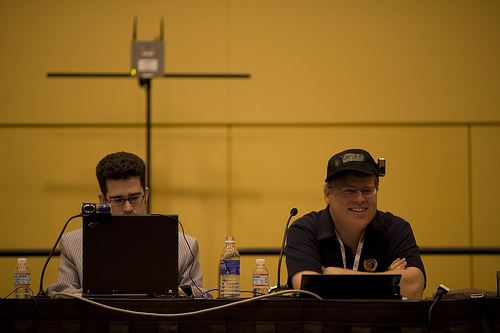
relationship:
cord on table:
[133, 302, 206, 321] [0, 292, 495, 331]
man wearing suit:
[275, 146, 421, 301] [43, 215, 215, 300]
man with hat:
[275, 146, 421, 301] [323, 146, 387, 180]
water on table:
[219, 233, 244, 303] [0, 292, 495, 331]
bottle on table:
[217, 235, 239, 297] [0, 293, 495, 328]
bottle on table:
[250, 256, 266, 293] [0, 293, 495, 328]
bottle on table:
[12, 256, 29, 296] [0, 293, 495, 328]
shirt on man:
[283, 208, 427, 302] [268, 138, 446, 309]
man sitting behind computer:
[62, 145, 215, 302] [65, 208, 192, 296]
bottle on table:
[217, 235, 239, 297] [1, 298, 498, 331]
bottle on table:
[250, 256, 266, 293] [1, 298, 498, 331]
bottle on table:
[12, 256, 29, 296] [1, 298, 498, 331]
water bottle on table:
[218, 235, 240, 294] [0, 293, 495, 328]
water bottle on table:
[253, 257, 268, 293] [0, 293, 495, 328]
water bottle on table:
[14, 251, 29, 294] [0, 293, 495, 328]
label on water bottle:
[218, 259, 240, 275] [253, 255, 269, 296]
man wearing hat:
[275, 146, 421, 301] [315, 136, 395, 187]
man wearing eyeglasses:
[62, 145, 215, 302] [98, 189, 151, 208]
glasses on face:
[327, 180, 377, 201] [337, 170, 374, 231]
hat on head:
[325, 145, 379, 195] [320, 147, 384, 229]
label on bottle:
[218, 259, 240, 275] [217, 235, 239, 297]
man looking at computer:
[62, 145, 215, 302] [65, 208, 192, 296]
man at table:
[275, 146, 421, 301] [1, 280, 475, 330]